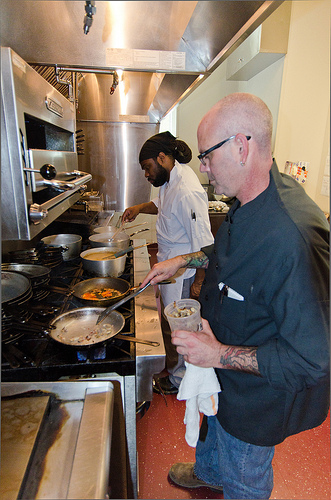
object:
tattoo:
[181, 251, 211, 269]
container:
[164, 298, 203, 332]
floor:
[135, 243, 330, 500]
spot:
[171, 444, 180, 450]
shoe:
[167, 461, 224, 494]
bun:
[173, 140, 192, 164]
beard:
[147, 166, 169, 187]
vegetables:
[81, 287, 122, 300]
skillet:
[72, 277, 172, 307]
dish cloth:
[284, 161, 307, 185]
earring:
[240, 161, 246, 166]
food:
[164, 300, 203, 331]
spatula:
[96, 279, 172, 325]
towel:
[177, 361, 222, 448]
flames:
[77, 348, 106, 361]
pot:
[80, 240, 155, 278]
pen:
[219, 285, 228, 304]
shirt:
[198, 159, 331, 446]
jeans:
[193, 416, 275, 499]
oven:
[0, 46, 165, 500]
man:
[168, 92, 331, 499]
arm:
[180, 243, 214, 269]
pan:
[48, 307, 160, 359]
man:
[121, 131, 214, 396]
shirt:
[151, 160, 215, 280]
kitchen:
[0, 0, 331, 498]